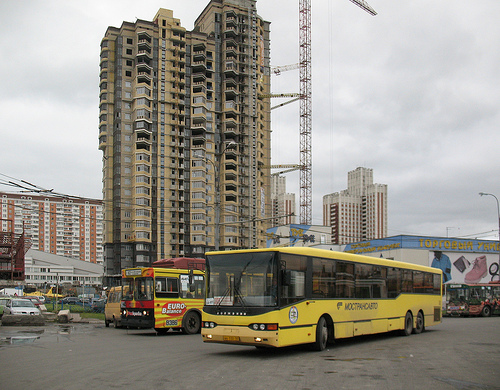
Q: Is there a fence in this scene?
A: No, there are no fences.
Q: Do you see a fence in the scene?
A: No, there are no fences.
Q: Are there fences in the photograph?
A: No, there are no fences.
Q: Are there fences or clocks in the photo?
A: No, there are no fences or clocks.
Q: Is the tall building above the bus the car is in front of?
A: Yes, the building is above the bus.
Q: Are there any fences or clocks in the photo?
A: No, there are no fences or clocks.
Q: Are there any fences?
A: No, there are no fences.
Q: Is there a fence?
A: No, there are no fences.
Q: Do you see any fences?
A: No, there are no fences.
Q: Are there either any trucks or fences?
A: No, there are no fences or trucks.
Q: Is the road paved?
A: Yes, the road is paved.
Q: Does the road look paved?
A: Yes, the road is paved.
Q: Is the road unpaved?
A: No, the road is paved.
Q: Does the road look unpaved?
A: No, the road is paved.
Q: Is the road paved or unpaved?
A: The road is paved.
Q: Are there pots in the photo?
A: No, there are no pots.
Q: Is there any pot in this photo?
A: No, there are no pots.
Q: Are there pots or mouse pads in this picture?
A: No, there are no pots or mouse pads.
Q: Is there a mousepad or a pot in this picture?
A: No, there are no pots or mouse pads.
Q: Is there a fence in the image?
A: No, there are no fences.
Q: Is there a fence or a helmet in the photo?
A: No, there are no fences or helmets.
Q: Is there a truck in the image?
A: No, there are no trucks.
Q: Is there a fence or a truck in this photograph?
A: No, there are no trucks or fences.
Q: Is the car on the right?
A: No, the car is on the left of the image.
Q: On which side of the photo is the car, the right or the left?
A: The car is on the left of the image.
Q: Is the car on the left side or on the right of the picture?
A: The car is on the left of the image.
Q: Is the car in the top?
A: No, the car is in the bottom of the image.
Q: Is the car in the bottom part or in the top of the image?
A: The car is in the bottom of the image.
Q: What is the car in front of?
A: The car is in front of the bus.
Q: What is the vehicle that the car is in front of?
A: The vehicle is a bus.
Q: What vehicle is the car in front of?
A: The car is in front of the bus.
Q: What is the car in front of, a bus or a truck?
A: The car is in front of a bus.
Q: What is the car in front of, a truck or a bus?
A: The car is in front of a bus.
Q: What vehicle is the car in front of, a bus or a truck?
A: The car is in front of a bus.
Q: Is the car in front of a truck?
A: No, the car is in front of the bus.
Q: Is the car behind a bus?
A: No, the car is in front of a bus.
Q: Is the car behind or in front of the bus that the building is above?
A: The car is in front of the bus.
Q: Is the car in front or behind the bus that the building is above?
A: The car is in front of the bus.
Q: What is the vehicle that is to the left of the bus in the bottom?
A: The vehicle is a car.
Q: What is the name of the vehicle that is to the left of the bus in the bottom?
A: The vehicle is a car.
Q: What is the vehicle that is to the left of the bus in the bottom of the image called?
A: The vehicle is a car.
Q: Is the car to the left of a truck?
A: No, the car is to the left of the bus.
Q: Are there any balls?
A: No, there are no balls.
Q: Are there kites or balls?
A: No, there are no balls or kites.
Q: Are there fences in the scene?
A: No, there are no fences.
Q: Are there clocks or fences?
A: No, there are no fences or clocks.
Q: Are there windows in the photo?
A: Yes, there is a window.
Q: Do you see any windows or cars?
A: Yes, there is a window.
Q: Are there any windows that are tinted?
A: Yes, there is a tinted window.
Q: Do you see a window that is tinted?
A: Yes, there is a window that is tinted.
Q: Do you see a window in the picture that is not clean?
A: Yes, there is a tinted window.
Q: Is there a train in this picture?
A: No, there are no trains.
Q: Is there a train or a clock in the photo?
A: No, there are no trains or clocks.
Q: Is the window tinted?
A: Yes, the window is tinted.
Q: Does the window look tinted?
A: Yes, the window is tinted.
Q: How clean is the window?
A: The window is tinted.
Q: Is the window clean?
A: No, the window is tinted.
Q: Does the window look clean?
A: No, the window is tinted.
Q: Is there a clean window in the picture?
A: No, there is a window but it is tinted.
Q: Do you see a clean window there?
A: No, there is a window but it is tinted.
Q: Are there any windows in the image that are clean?
A: No, there is a window but it is tinted.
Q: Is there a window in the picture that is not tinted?
A: No, there is a window but it is tinted.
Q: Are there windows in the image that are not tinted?
A: No, there is a window but it is tinted.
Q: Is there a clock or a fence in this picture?
A: No, there are no fences or clocks.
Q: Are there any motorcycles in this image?
A: No, there are no motorcycles.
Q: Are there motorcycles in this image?
A: No, there are no motorcycles.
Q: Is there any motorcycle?
A: No, there are no motorcycles.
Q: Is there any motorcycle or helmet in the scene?
A: No, there are no motorcycles or helmets.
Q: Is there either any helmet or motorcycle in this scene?
A: No, there are no motorcycles or helmets.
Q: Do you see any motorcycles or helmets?
A: No, there are no motorcycles or helmets.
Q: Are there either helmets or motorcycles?
A: No, there are no motorcycles or helmets.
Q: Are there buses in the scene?
A: Yes, there is a bus.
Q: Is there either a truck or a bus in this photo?
A: Yes, there is a bus.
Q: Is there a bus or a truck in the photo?
A: Yes, there is a bus.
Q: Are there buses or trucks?
A: Yes, there is a bus.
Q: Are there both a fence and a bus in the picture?
A: No, there is a bus but no fences.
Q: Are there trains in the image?
A: No, there are no trains.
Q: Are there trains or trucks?
A: No, there are no trains or trucks.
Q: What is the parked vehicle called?
A: The vehicle is a bus.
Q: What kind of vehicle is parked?
A: The vehicle is a bus.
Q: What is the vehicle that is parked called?
A: The vehicle is a bus.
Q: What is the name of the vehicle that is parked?
A: The vehicle is a bus.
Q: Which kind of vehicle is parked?
A: The vehicle is a bus.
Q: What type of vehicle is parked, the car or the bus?
A: The bus is parked.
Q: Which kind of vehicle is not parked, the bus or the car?
A: The car is not parked.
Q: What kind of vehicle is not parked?
A: The vehicle is a car.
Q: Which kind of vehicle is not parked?
A: The vehicle is a car.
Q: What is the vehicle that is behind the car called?
A: The vehicle is a bus.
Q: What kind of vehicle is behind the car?
A: The vehicle is a bus.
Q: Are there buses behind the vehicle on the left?
A: Yes, there is a bus behind the car.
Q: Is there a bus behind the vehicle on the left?
A: Yes, there is a bus behind the car.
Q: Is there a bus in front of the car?
A: No, the bus is behind the car.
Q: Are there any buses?
A: Yes, there is a bus.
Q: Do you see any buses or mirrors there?
A: Yes, there is a bus.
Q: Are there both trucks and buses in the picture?
A: No, there is a bus but no trucks.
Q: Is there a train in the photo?
A: No, there are no trains.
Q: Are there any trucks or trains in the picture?
A: No, there are no trains or trucks.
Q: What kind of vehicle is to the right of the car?
A: The vehicle is a bus.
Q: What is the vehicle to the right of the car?
A: The vehicle is a bus.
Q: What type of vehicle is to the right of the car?
A: The vehicle is a bus.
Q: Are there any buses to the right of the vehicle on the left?
A: Yes, there is a bus to the right of the car.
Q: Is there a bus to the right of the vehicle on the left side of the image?
A: Yes, there is a bus to the right of the car.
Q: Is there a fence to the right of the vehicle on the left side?
A: No, there is a bus to the right of the car.